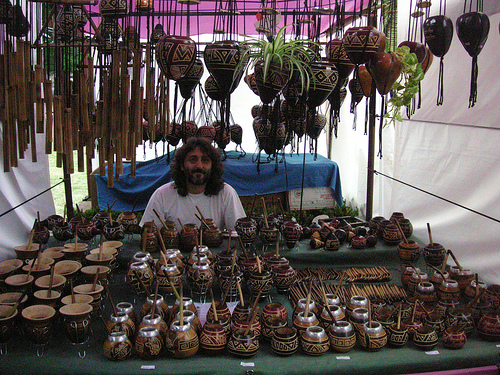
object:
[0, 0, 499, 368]
tent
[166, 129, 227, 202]
old guy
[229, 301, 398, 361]
bowls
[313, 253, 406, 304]
wood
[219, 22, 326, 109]
plant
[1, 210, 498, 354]
pottery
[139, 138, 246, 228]
man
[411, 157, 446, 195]
ground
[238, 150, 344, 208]
table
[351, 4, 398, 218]
pole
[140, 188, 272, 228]
tshirt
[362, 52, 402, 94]
red pot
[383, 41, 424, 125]
plant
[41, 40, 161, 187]
chimes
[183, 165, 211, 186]
beard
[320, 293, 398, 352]
pot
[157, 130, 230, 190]
curly hair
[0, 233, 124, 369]
goblets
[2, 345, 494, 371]
table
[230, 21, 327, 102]
fern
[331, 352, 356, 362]
sticker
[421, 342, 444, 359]
sticker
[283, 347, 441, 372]
tables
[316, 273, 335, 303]
stick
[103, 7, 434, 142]
wind chimes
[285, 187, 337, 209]
box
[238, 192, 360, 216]
grass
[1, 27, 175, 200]
bells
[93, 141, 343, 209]
tarp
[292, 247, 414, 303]
smashers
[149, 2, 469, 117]
macrame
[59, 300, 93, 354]
goblet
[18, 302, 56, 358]
goblet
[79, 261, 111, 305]
goblet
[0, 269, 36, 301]
goblet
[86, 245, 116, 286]
goblet